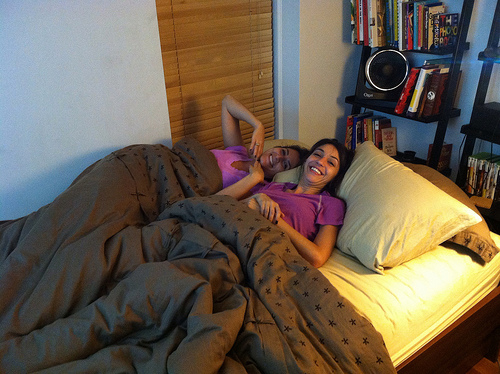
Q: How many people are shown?
A: Two.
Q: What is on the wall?
A: A window.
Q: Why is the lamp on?
A: To provide light.